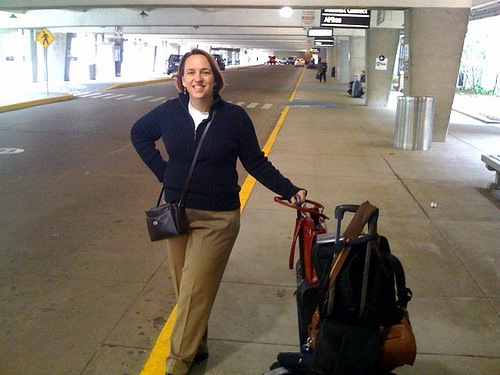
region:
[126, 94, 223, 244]
a leather, crossbody purse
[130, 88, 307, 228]
a black zip up sweater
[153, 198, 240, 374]
a pair of beige pants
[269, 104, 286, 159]
a yellow stripe on ground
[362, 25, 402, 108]
a large concrete pillar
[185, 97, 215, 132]
a white tee shirt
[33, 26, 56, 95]
a yellow sign on a pole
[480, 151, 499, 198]
a wooden bench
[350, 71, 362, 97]
a blue suitcase in background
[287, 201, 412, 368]
a black suit case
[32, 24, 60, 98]
A yellow crosswalk sign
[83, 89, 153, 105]
Crosswalk on the street.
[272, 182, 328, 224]
A red purse handle.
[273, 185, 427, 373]
A pile of luggage.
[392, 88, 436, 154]
A silver trash can.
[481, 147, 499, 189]
The end of a bench.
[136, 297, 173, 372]
The yellow street curb.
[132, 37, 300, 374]
A women standing cross legged.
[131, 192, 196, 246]
A brown leather purse.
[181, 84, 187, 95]
A earing hangs down.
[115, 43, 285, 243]
She is wearing a blue shirt.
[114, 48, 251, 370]
She is wearing tan pants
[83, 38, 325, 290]
She has a brown purse.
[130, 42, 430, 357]
She is holding luggage.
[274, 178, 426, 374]
The suitcase is black.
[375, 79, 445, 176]
The trash can is silver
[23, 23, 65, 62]
The sign is yellow.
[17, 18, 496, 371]
She is at the airport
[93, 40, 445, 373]
She is standing on the sidewalk.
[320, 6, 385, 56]
The sign is lite up.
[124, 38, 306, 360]
an women standing on the road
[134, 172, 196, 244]
the brown colored side bag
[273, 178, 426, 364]
the luggage bag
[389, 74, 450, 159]
the steel dustbin on the roadside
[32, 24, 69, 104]
the sign board with yellow color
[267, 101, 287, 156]
the yellow colored paint on the road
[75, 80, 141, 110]
the white colored painting used to show the pedestrain walk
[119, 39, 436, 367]
an women standing with the luggage bags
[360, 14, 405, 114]
the poles of an bridge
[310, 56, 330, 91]
a man walking on the platform with luggage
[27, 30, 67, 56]
a yellow pedestrian sign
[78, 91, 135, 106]
crossing mark on street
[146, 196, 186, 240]
part of black purse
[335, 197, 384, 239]
handle on luggage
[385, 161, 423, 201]
line on sidewalk pavement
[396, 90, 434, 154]
a silver container on sidewalk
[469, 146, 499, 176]
end portion of bench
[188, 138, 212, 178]
strap on black purse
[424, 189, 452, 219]
paper on the sidewalk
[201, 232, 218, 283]
portion of woman's slacks